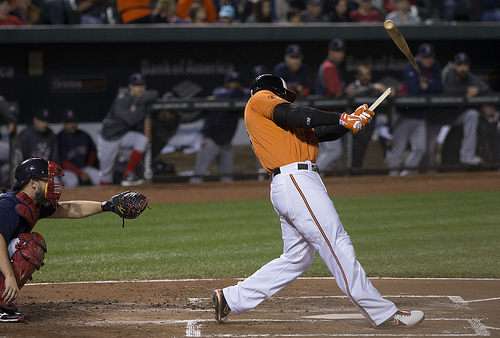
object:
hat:
[249, 73, 293, 98]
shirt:
[243, 89, 320, 173]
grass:
[67, 225, 237, 273]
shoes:
[374, 309, 422, 328]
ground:
[451, 110, 469, 127]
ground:
[394, 170, 439, 218]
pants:
[222, 161, 398, 328]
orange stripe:
[287, 173, 383, 327]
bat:
[381, 18, 427, 82]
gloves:
[338, 111, 365, 135]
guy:
[97, 73, 157, 188]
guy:
[56, 107, 102, 189]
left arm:
[42, 198, 108, 220]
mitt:
[101, 189, 147, 219]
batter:
[212, 71, 426, 327]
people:
[1, 1, 498, 28]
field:
[1, 171, 498, 336]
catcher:
[1, 156, 151, 324]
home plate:
[301, 310, 366, 321]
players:
[46, 111, 112, 187]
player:
[431, 52, 498, 169]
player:
[385, 40, 444, 174]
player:
[344, 66, 396, 165]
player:
[316, 36, 373, 99]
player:
[191, 74, 263, 186]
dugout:
[2, 20, 500, 192]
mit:
[100, 190, 154, 220]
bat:
[354, 87, 392, 132]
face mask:
[47, 160, 64, 209]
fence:
[139, 92, 500, 182]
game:
[36, 45, 477, 334]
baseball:
[0, 27, 498, 336]